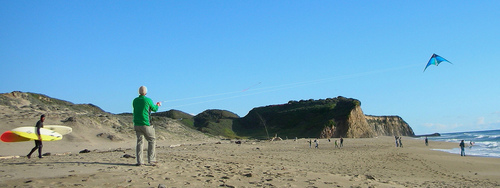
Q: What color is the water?
A: Light blue.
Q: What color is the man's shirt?
A: Green.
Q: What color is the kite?
A: Blue.